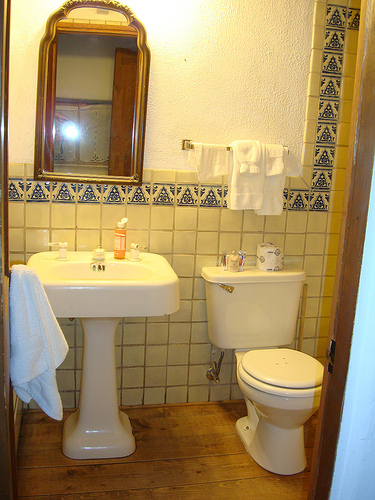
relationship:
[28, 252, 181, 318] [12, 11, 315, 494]
sink in bathroom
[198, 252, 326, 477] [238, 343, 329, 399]
toilet with lid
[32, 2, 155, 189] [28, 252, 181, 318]
mirror above sink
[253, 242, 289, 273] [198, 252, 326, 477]
toilet paper on back of toilet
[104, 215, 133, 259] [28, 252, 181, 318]
bottle on sink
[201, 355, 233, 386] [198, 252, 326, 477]
hookup for toilet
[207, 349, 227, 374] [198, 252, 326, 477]
intake hose of toilet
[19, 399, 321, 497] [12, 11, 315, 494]
floor of bathroom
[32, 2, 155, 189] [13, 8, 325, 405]
mirror on wall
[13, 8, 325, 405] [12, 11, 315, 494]
wall of bathroom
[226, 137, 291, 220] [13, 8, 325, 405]
towels hanging on wall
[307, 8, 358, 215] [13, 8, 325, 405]
tiles on wall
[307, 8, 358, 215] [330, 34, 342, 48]
tiles with triangles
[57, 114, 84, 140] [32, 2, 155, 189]
reflection in mirror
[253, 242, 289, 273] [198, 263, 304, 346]
toilet paper on tank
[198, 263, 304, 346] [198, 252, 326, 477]
tank of toilet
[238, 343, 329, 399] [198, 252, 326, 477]
lid of toilet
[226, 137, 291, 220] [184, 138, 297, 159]
towels on rack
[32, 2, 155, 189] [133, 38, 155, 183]
mirror has trim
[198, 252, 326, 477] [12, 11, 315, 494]
toilet in bathroom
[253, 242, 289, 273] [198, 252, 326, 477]
toilet paper on toilet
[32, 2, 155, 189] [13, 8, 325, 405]
mirror hanging on wall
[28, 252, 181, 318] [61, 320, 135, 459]
sink on top of pedestal